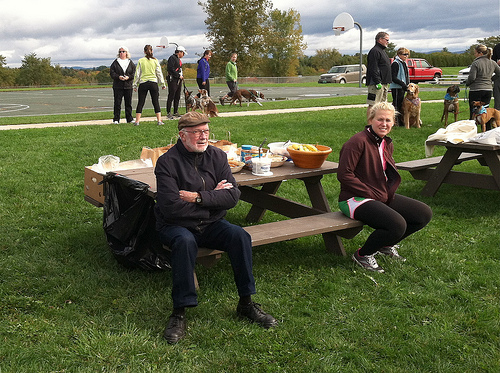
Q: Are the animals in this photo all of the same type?
A: Yes, all the animals are dogs.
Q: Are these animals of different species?
A: No, all the animals are dogs.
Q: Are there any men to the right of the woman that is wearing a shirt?
A: Yes, there is a man to the right of the woman.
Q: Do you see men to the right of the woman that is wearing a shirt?
A: Yes, there is a man to the right of the woman.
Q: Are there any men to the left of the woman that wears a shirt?
A: No, the man is to the right of the woman.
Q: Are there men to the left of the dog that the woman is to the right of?
A: Yes, there is a man to the left of the dog.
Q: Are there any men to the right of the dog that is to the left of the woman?
A: No, the man is to the left of the dog.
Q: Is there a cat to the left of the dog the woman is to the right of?
A: No, there is a man to the left of the dog.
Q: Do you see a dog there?
A: Yes, there is a dog.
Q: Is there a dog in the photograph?
A: Yes, there is a dog.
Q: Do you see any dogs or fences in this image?
A: Yes, there is a dog.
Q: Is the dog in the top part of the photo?
A: Yes, the dog is in the top of the image.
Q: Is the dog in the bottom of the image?
A: No, the dog is in the top of the image.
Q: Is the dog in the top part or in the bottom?
A: The dog is in the top of the image.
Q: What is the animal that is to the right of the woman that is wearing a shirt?
A: The animal is a dog.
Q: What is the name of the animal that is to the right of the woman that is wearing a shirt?
A: The animal is a dog.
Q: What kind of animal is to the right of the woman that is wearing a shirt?
A: The animal is a dog.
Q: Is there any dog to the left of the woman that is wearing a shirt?
A: No, the dog is to the right of the woman.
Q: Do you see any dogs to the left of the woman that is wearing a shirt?
A: No, the dog is to the right of the woman.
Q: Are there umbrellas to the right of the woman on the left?
A: No, there is a dog to the right of the woman.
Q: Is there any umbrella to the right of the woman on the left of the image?
A: No, there is a dog to the right of the woman.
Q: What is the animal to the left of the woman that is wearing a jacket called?
A: The animal is a dog.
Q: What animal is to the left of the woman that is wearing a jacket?
A: The animal is a dog.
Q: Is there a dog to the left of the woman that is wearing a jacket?
A: Yes, there is a dog to the left of the woman.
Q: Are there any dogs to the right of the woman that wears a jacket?
A: No, the dog is to the left of the woman.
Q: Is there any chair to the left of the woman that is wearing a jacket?
A: No, there is a dog to the left of the woman.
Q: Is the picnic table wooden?
A: Yes, the picnic table is wooden.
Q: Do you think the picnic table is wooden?
A: Yes, the picnic table is wooden.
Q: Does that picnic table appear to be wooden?
A: Yes, the picnic table is wooden.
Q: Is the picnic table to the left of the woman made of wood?
A: Yes, the picnic table is made of wood.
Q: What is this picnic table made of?
A: The picnic table is made of wood.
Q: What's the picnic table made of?
A: The picnic table is made of wood.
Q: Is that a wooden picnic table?
A: Yes, that is a wooden picnic table.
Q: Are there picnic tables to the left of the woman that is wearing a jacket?
A: Yes, there is a picnic table to the left of the woman.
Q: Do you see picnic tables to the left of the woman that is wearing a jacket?
A: Yes, there is a picnic table to the left of the woman.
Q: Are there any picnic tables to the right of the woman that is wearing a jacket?
A: No, the picnic table is to the left of the woman.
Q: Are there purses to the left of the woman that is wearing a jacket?
A: No, there is a picnic table to the left of the woman.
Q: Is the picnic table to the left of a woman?
A: Yes, the picnic table is to the left of a woman.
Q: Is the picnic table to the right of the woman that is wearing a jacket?
A: No, the picnic table is to the left of the woman.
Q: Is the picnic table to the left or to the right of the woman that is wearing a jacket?
A: The picnic table is to the left of the woman.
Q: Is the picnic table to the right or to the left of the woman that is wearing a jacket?
A: The picnic table is to the left of the woman.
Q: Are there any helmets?
A: No, there are no helmets.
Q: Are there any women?
A: Yes, there is a woman.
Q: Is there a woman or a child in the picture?
A: Yes, there is a woman.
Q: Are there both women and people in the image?
A: Yes, there are both a woman and people.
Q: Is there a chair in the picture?
A: No, there are no chairs.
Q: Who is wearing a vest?
A: The woman is wearing a vest.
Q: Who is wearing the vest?
A: The woman is wearing a vest.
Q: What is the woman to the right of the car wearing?
A: The woman is wearing a vest.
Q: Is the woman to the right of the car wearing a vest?
A: Yes, the woman is wearing a vest.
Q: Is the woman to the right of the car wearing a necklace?
A: No, the woman is wearing a vest.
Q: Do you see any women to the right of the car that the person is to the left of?
A: Yes, there is a woman to the right of the car.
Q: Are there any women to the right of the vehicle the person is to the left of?
A: Yes, there is a woman to the right of the car.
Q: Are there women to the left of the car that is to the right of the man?
A: No, the woman is to the right of the car.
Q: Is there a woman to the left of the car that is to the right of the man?
A: No, the woman is to the right of the car.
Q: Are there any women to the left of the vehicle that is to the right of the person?
A: No, the woman is to the right of the car.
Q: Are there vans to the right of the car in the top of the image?
A: No, there is a woman to the right of the car.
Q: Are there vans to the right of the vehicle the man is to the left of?
A: No, there is a woman to the right of the car.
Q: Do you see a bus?
A: No, there are no buses.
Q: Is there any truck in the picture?
A: Yes, there is a truck.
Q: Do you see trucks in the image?
A: Yes, there is a truck.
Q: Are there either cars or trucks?
A: Yes, there is a truck.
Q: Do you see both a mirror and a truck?
A: No, there is a truck but no mirrors.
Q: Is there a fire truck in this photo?
A: No, there are no fire trucks.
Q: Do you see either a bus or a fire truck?
A: No, there are no fire trucks or buses.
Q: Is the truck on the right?
A: Yes, the truck is on the right of the image.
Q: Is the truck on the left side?
A: No, the truck is on the right of the image.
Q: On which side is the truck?
A: The truck is on the right of the image.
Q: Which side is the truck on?
A: The truck is on the right of the image.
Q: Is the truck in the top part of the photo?
A: Yes, the truck is in the top of the image.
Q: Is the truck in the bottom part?
A: No, the truck is in the top of the image.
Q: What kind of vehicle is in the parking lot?
A: The vehicle is a truck.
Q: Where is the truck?
A: The truck is in the parking lot.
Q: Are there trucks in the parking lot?
A: Yes, there is a truck in the parking lot.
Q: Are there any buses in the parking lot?
A: No, there is a truck in the parking lot.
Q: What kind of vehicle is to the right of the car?
A: The vehicle is a truck.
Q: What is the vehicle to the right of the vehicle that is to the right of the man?
A: The vehicle is a truck.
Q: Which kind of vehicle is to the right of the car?
A: The vehicle is a truck.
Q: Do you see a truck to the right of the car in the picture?
A: Yes, there is a truck to the right of the car.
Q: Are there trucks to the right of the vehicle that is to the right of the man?
A: Yes, there is a truck to the right of the car.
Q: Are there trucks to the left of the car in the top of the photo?
A: No, the truck is to the right of the car.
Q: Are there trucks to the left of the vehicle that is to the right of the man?
A: No, the truck is to the right of the car.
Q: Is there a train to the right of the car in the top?
A: No, there is a truck to the right of the car.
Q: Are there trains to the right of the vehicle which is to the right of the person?
A: No, there is a truck to the right of the car.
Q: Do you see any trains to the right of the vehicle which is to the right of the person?
A: No, there is a truck to the right of the car.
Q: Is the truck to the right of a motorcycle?
A: No, the truck is to the right of the car.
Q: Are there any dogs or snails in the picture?
A: Yes, there is a dog.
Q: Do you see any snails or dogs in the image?
A: Yes, there is a dog.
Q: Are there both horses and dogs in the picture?
A: No, there is a dog but no horses.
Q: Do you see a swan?
A: No, there are no swans.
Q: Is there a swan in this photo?
A: No, there are no swans.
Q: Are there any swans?
A: No, there are no swans.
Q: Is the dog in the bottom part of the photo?
A: No, the dog is in the top of the image.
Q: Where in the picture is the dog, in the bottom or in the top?
A: The dog is in the top of the image.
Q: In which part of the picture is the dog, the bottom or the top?
A: The dog is in the top of the image.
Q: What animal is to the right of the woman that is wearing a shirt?
A: The animal is a dog.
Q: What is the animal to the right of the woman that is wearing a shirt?
A: The animal is a dog.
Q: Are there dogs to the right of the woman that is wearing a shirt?
A: Yes, there is a dog to the right of the woman.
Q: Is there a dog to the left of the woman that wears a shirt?
A: No, the dog is to the right of the woman.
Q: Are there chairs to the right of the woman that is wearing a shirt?
A: No, there is a dog to the right of the woman.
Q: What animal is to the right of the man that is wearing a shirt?
A: The animal is a dog.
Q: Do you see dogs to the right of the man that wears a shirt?
A: Yes, there is a dog to the right of the man.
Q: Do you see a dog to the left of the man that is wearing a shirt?
A: No, the dog is to the right of the man.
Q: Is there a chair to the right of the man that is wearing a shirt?
A: No, there is a dog to the right of the man.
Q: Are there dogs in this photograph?
A: Yes, there is a dog.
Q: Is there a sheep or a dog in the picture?
A: Yes, there is a dog.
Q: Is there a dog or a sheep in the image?
A: Yes, there is a dog.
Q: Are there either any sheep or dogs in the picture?
A: Yes, there is a dog.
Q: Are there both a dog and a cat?
A: No, there is a dog but no cats.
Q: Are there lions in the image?
A: No, there are no lions.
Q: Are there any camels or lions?
A: No, there are no lions or camels.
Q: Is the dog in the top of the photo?
A: Yes, the dog is in the top of the image.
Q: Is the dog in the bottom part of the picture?
A: No, the dog is in the top of the image.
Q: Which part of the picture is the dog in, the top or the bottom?
A: The dog is in the top of the image.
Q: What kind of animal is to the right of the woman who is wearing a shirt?
A: The animal is a dog.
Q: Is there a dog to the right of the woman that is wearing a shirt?
A: Yes, there is a dog to the right of the woman.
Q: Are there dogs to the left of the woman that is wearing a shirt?
A: No, the dog is to the right of the woman.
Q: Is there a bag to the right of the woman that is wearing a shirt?
A: No, there is a dog to the right of the woman.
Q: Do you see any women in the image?
A: Yes, there is a woman.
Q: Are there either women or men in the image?
A: Yes, there is a woman.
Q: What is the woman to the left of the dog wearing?
A: The woman is wearing a shirt.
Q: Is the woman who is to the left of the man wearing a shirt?
A: Yes, the woman is wearing a shirt.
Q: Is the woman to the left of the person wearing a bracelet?
A: No, the woman is wearing a shirt.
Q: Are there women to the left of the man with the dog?
A: Yes, there is a woman to the left of the man.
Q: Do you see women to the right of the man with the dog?
A: No, the woman is to the left of the man.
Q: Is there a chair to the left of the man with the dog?
A: No, there is a woman to the left of the man.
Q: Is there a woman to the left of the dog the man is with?
A: Yes, there is a woman to the left of the dog.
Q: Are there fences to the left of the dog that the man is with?
A: No, there is a woman to the left of the dog.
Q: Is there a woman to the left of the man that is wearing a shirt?
A: Yes, there is a woman to the left of the man.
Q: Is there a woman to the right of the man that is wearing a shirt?
A: No, the woman is to the left of the man.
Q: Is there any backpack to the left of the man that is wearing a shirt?
A: No, there is a woman to the left of the man.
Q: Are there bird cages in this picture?
A: No, there are no bird cages.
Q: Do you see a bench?
A: Yes, there is a bench.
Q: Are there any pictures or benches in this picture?
A: Yes, there is a bench.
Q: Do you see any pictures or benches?
A: Yes, there is a bench.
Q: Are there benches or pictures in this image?
A: Yes, there is a bench.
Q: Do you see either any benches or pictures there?
A: Yes, there is a bench.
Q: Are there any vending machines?
A: No, there are no vending machines.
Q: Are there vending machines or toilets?
A: No, there are no vending machines or toilets.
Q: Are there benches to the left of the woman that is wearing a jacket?
A: Yes, there is a bench to the left of the woman.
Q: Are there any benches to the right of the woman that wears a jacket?
A: No, the bench is to the left of the woman.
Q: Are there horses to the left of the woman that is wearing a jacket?
A: No, there is a bench to the left of the woman.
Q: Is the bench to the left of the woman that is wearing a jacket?
A: Yes, the bench is to the left of the woman.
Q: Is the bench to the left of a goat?
A: No, the bench is to the left of the woman.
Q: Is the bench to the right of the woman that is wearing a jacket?
A: No, the bench is to the left of the woman.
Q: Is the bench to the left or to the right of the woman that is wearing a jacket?
A: The bench is to the left of the woman.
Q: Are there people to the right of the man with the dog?
A: Yes, there is a person to the right of the man.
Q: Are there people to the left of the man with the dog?
A: No, the person is to the right of the man.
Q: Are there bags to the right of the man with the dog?
A: No, there is a person to the right of the man.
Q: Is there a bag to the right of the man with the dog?
A: No, there is a person to the right of the man.